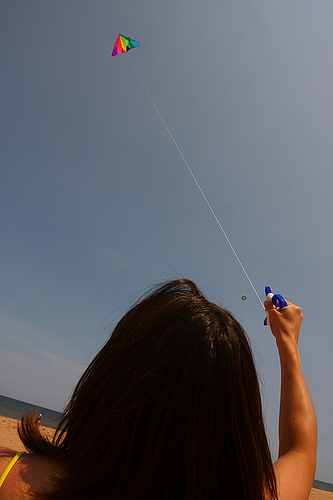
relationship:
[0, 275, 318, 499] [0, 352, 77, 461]
person walking beach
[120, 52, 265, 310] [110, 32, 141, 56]
string of kite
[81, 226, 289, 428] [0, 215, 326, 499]
head of woman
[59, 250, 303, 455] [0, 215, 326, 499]
hair of woman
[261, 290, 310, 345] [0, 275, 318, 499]
hand of person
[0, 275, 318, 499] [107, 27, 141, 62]
person flying kite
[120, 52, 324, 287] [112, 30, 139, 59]
string holds kite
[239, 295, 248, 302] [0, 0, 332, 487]
kite in blue sky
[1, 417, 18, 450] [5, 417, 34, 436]
sand on beach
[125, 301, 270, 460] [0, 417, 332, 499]
person on sand